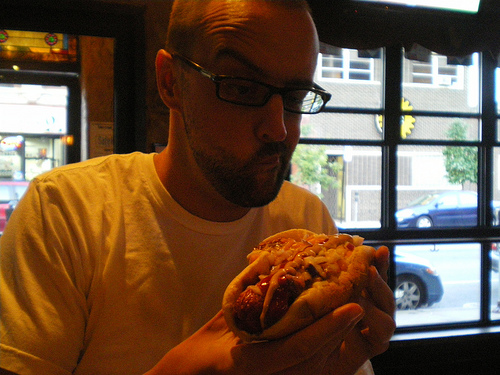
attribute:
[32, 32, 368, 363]
man — confused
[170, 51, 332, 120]
glasses — black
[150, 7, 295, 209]
head — shaven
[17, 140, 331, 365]
shirt — white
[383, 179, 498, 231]
car — blue, parked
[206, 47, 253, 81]
eyebrow — raised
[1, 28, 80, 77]
window — stained glass